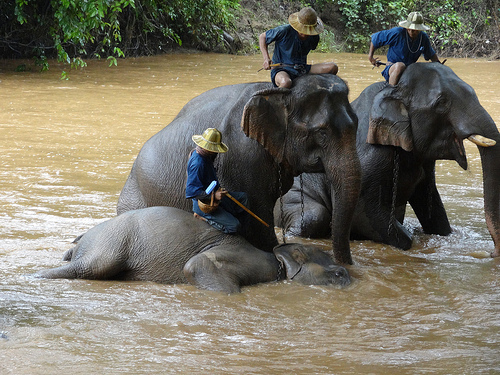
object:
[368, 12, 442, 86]
person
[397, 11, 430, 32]
hat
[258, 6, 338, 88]
person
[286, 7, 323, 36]
hat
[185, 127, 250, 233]
person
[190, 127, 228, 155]
hat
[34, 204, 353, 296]
elephant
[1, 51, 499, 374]
water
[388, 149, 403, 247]
chains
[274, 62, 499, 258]
elephant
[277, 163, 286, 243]
chains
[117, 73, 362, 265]
elephant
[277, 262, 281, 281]
chains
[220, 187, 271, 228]
stick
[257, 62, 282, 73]
stick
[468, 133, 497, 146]
tusk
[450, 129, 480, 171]
mouth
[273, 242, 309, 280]
ear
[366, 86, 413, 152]
ear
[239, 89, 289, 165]
ear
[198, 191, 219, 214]
basket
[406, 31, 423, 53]
necklace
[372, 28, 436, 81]
outfit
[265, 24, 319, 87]
outfit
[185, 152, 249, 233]
outfit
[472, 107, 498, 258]
trunk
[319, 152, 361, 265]
trunk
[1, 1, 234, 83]
tree branches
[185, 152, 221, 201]
shirt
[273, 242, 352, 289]
head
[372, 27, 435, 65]
shirt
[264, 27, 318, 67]
shirt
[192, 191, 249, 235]
jeans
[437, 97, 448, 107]
eye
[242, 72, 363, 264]
head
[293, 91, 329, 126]
dent